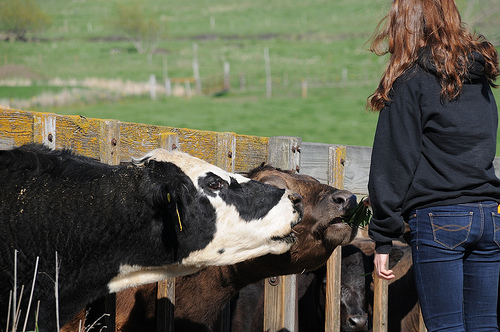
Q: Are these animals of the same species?
A: Yes, all the animals are cows.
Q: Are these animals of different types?
A: No, all the animals are cows.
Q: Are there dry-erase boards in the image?
A: No, there are no dry-erase boards.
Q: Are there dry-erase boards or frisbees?
A: No, there are no dry-erase boards or frisbees.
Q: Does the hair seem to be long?
A: Yes, the hair is long.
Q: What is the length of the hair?
A: The hair is long.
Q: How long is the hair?
A: The hair is long.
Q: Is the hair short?
A: No, the hair is long.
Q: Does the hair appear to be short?
A: No, the hair is long.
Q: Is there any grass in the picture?
A: Yes, there is grass.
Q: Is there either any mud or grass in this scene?
A: Yes, there is grass.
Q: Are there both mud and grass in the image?
A: No, there is grass but no mud.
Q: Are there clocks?
A: No, there are no clocks.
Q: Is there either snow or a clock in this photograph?
A: No, there are no clocks or snow.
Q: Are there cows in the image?
A: Yes, there is a cow.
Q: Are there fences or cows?
A: Yes, there is a cow.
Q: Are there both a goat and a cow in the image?
A: No, there is a cow but no goats.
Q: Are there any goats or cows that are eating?
A: Yes, the cow is eating.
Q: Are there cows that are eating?
A: Yes, there is a cow that is eating.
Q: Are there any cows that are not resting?
A: Yes, there is a cow that is eating.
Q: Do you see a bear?
A: No, there are no bears.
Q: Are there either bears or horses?
A: No, there are no bears or horses.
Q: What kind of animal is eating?
A: The animal is a cow.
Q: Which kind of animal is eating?
A: The animal is a cow.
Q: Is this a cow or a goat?
A: This is a cow.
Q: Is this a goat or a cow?
A: This is a cow.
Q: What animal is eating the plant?
A: The cow is eating the plant.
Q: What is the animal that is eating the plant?
A: The animal is a cow.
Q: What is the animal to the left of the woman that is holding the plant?
A: The animal is a cow.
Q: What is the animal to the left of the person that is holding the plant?
A: The animal is a cow.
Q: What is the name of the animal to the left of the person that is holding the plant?
A: The animal is a cow.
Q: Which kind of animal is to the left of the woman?
A: The animal is a cow.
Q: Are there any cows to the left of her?
A: Yes, there is a cow to the left of the woman.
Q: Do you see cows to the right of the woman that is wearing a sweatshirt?
A: No, the cow is to the left of the woman.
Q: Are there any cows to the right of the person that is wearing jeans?
A: No, the cow is to the left of the woman.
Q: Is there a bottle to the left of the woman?
A: No, there is a cow to the left of the woman.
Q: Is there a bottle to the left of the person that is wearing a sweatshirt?
A: No, there is a cow to the left of the woman.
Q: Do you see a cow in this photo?
A: Yes, there is a cow.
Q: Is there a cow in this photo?
A: Yes, there is a cow.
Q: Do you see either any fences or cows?
A: Yes, there is a cow.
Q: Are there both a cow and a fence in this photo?
A: Yes, there are both a cow and a fence.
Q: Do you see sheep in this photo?
A: No, there are no sheep.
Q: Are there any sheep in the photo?
A: No, there are no sheep.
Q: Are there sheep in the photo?
A: No, there are no sheep.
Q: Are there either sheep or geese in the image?
A: No, there are no sheep or geese.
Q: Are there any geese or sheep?
A: No, there are no sheep or geese.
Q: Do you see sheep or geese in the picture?
A: No, there are no sheep or geese.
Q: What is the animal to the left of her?
A: The animal is a cow.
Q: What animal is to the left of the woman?
A: The animal is a cow.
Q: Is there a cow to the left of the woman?
A: Yes, there is a cow to the left of the woman.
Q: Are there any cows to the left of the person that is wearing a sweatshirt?
A: Yes, there is a cow to the left of the woman.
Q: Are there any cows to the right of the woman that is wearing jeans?
A: No, the cow is to the left of the woman.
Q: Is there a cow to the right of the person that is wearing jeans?
A: No, the cow is to the left of the woman.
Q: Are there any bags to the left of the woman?
A: No, there is a cow to the left of the woman.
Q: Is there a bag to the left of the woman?
A: No, there is a cow to the left of the woman.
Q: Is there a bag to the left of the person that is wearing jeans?
A: No, there is a cow to the left of the woman.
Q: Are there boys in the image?
A: No, there are no boys.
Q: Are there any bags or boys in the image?
A: No, there are no boys or bags.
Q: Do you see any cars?
A: No, there are no cars.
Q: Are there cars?
A: No, there are no cars.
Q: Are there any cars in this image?
A: No, there are no cars.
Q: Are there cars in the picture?
A: No, there are no cars.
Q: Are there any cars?
A: No, there are no cars.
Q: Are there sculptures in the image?
A: No, there are no sculptures.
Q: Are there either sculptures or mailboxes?
A: No, there are no sculptures or mailboxes.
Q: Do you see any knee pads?
A: No, there are no knee pads.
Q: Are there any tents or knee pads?
A: No, there are no knee pads or tents.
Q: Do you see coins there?
A: No, there are no coins.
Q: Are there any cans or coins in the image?
A: No, there are no coins or cans.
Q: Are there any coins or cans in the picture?
A: No, there are no coins or cans.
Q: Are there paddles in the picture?
A: No, there are no paddles.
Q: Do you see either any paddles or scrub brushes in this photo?
A: No, there are no paddles or scrub brushes.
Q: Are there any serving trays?
A: No, there are no serving trays.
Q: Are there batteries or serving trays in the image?
A: No, there are no serving trays or batteries.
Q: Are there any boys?
A: No, there are no boys.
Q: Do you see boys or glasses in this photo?
A: No, there are no boys or glasses.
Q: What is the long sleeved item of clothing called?
A: The clothing item is a sweatshirt.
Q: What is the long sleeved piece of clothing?
A: The clothing item is a sweatshirt.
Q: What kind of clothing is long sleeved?
A: The clothing is a sweatshirt.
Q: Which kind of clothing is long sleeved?
A: The clothing is a sweatshirt.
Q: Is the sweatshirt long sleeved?
A: Yes, the sweatshirt is long sleeved.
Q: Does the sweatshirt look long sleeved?
A: Yes, the sweatshirt is long sleeved.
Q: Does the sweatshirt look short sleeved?
A: No, the sweatshirt is long sleeved.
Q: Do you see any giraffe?
A: No, there are no giraffes.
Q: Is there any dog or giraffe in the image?
A: No, there are no giraffes or dogs.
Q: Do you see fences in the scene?
A: Yes, there is a fence.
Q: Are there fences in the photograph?
A: Yes, there is a fence.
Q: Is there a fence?
A: Yes, there is a fence.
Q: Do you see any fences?
A: Yes, there is a fence.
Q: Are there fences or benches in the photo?
A: Yes, there is a fence.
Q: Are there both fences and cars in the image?
A: No, there is a fence but no cars.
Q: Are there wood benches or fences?
A: Yes, there is a wood fence.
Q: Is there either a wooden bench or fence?
A: Yes, there is a wood fence.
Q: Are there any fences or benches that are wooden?
A: Yes, the fence is wooden.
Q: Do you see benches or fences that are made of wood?
A: Yes, the fence is made of wood.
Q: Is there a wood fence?
A: Yes, there is a fence that is made of wood.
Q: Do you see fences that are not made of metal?
A: Yes, there is a fence that is made of wood.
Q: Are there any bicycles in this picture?
A: No, there are no bicycles.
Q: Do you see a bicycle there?
A: No, there are no bicycles.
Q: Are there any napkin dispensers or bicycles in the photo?
A: No, there are no bicycles or napkin dispensers.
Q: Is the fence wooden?
A: Yes, the fence is wooden.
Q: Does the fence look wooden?
A: Yes, the fence is wooden.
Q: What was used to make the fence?
A: The fence is made of wood.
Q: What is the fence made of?
A: The fence is made of wood.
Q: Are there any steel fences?
A: No, there is a fence but it is made of wood.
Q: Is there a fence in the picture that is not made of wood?
A: No, there is a fence but it is made of wood.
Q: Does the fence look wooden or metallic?
A: The fence is wooden.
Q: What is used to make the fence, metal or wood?
A: The fence is made of wood.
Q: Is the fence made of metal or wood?
A: The fence is made of wood.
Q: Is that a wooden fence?
A: Yes, that is a wooden fence.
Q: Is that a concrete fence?
A: No, that is a wooden fence.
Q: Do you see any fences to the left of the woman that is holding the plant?
A: Yes, there is a fence to the left of the woman.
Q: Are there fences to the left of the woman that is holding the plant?
A: Yes, there is a fence to the left of the woman.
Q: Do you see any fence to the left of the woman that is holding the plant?
A: Yes, there is a fence to the left of the woman.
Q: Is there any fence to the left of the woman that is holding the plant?
A: Yes, there is a fence to the left of the woman.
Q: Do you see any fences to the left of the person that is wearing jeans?
A: Yes, there is a fence to the left of the woman.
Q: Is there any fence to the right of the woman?
A: No, the fence is to the left of the woman.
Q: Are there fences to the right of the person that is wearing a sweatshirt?
A: No, the fence is to the left of the woman.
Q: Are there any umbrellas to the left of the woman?
A: No, there is a fence to the left of the woman.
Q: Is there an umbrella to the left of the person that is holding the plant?
A: No, there is a fence to the left of the woman.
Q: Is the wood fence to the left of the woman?
A: Yes, the fence is to the left of the woman.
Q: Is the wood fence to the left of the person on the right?
A: Yes, the fence is to the left of the woman.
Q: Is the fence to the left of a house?
A: No, the fence is to the left of the woman.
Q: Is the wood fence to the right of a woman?
A: No, the fence is to the left of a woman.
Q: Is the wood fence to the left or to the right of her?
A: The fence is to the left of the woman.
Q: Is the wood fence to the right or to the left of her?
A: The fence is to the left of the woman.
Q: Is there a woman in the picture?
A: Yes, there is a woman.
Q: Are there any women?
A: Yes, there is a woman.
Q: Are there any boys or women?
A: Yes, there is a woman.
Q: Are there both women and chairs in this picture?
A: No, there is a woman but no chairs.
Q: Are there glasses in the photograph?
A: No, there are no glasses.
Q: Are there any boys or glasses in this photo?
A: No, there are no glasses or boys.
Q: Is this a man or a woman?
A: This is a woman.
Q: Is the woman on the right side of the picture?
A: Yes, the woman is on the right of the image.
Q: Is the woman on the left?
A: No, the woman is on the right of the image.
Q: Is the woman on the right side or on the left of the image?
A: The woman is on the right of the image.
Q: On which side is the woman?
A: The woman is on the right of the image.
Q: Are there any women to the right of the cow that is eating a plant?
A: Yes, there is a woman to the right of the cow.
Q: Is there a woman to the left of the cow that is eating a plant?
A: No, the woman is to the right of the cow.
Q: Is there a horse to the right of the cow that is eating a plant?
A: No, there is a woman to the right of the cow.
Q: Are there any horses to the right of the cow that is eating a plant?
A: No, there is a woman to the right of the cow.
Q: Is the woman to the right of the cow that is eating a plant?
A: Yes, the woman is to the right of the cow.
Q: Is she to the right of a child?
A: No, the woman is to the right of the cow.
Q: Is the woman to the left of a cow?
A: No, the woman is to the right of a cow.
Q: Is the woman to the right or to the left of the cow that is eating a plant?
A: The woman is to the right of the cow.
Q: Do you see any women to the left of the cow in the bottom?
A: No, the woman is to the right of the cow.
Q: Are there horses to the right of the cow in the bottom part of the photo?
A: No, there is a woman to the right of the cow.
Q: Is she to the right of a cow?
A: Yes, the woman is to the right of a cow.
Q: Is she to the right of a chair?
A: No, the woman is to the right of a cow.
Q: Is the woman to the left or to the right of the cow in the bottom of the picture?
A: The woman is to the right of the cow.